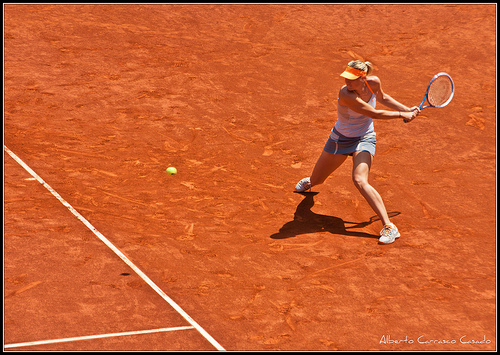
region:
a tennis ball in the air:
[133, 119, 208, 204]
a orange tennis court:
[58, 73, 298, 134]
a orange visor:
[328, 53, 368, 90]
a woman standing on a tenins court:
[224, 29, 426, 261]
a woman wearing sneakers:
[293, 50, 442, 257]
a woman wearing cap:
[303, 35, 401, 92]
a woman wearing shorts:
[288, 127, 430, 168]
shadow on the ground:
[265, 190, 332, 262]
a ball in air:
[156, 130, 180, 182]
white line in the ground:
[104, 232, 219, 332]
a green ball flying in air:
[137, 128, 203, 210]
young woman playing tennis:
[295, 59, 455, 244]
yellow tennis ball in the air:
[165, 166, 177, 176]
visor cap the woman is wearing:
[340, 67, 367, 79]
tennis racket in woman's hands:
[402, 70, 455, 122]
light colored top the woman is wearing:
[332, 81, 374, 137]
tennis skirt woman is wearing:
[322, 124, 376, 157]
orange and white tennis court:
[0, 1, 497, 352]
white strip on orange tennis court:
[2, 145, 229, 352]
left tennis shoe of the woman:
[373, 223, 400, 245]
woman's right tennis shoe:
[295, 175, 311, 192]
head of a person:
[332, 40, 387, 93]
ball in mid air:
[145, 145, 199, 191]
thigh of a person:
[303, 135, 365, 179]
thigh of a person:
[340, 141, 402, 181]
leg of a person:
[296, 172, 321, 189]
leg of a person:
[354, 174, 419, 229]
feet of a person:
[291, 170, 316, 195]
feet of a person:
[376, 213, 407, 247]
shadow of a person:
[300, 210, 339, 234]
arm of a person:
[354, 94, 406, 125]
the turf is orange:
[62, 34, 389, 354]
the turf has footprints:
[46, 79, 278, 332]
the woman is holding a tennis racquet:
[304, 44, 459, 134]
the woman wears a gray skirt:
[292, 103, 496, 250]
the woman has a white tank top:
[317, 90, 490, 202]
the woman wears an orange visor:
[325, 55, 409, 122]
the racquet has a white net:
[404, 74, 494, 154]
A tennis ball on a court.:
[164, 163, 178, 177]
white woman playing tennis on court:
[150, 43, 466, 290]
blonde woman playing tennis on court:
[133, 42, 475, 292]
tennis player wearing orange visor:
[297, 47, 447, 257]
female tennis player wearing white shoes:
[276, 46, 478, 284]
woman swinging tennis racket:
[276, 43, 476, 269]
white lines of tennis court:
[10, 132, 224, 343]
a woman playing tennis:
[286, 47, 446, 242]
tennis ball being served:
[154, 158, 187, 181]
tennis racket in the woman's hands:
[404, 66, 456, 126]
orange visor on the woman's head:
[338, 64, 368, 79]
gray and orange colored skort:
[324, 123, 376, 155]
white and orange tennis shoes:
[377, 225, 402, 246]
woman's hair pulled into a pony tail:
[349, 57, 376, 72]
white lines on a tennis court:
[99, 240, 198, 346]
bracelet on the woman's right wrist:
[394, 111, 405, 117]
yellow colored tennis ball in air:
[161, 161, 183, 179]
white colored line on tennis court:
[6, 139, 231, 344]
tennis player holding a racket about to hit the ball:
[276, 42, 465, 252]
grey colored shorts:
[318, 124, 381, 161]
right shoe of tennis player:
[290, 172, 321, 193]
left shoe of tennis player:
[373, 214, 401, 251]